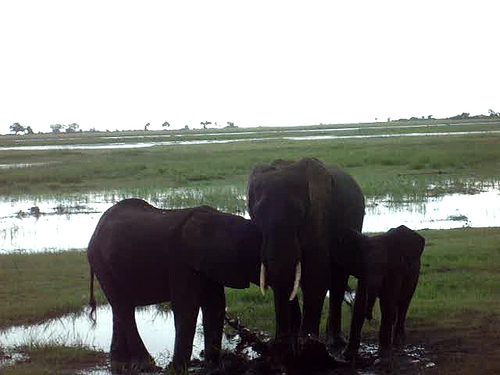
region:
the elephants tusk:
[290, 267, 308, 297]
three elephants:
[87, 153, 438, 366]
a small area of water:
[37, 309, 100, 346]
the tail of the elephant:
[82, 265, 96, 316]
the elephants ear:
[304, 152, 344, 219]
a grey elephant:
[94, 200, 241, 302]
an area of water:
[385, 180, 498, 229]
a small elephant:
[352, 225, 423, 344]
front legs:
[172, 305, 234, 363]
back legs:
[105, 311, 160, 368]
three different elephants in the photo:
[104, 148, 454, 331]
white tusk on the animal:
[283, 252, 313, 305]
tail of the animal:
[71, 264, 108, 323]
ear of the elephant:
[301, 158, 336, 210]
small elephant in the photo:
[346, 207, 416, 314]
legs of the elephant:
[75, 300, 235, 365]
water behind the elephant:
[440, 190, 480, 225]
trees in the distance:
[30, 110, 220, 145]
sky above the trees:
[265, 85, 310, 115]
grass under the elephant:
[435, 268, 477, 318]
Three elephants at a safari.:
[71, 141, 446, 371]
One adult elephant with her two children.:
[70, 128, 444, 368]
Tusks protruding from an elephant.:
[252, 239, 317, 306]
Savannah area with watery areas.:
[7, 114, 496, 328]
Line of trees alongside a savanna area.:
[3, 108, 498, 132]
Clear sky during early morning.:
[4, 40, 489, 118]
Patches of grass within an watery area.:
[370, 158, 482, 217]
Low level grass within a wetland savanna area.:
[405, 230, 492, 320]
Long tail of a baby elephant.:
[70, 246, 112, 338]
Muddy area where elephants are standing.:
[275, 320, 429, 373]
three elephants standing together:
[86, 148, 434, 368]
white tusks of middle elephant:
[247, 253, 319, 298]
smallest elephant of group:
[347, 218, 422, 355]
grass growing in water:
[43, 173, 471, 231]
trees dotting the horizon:
[8, 111, 494, 128]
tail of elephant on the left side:
[82, 255, 102, 314]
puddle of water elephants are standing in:
[7, 291, 398, 373]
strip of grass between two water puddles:
[12, 248, 489, 315]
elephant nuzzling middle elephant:
[87, 198, 269, 360]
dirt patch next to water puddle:
[355, 313, 495, 373]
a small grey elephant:
[86, 195, 258, 369]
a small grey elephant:
[346, 223, 426, 355]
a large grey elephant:
[246, 160, 366, 367]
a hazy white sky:
[0, 0, 497, 135]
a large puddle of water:
[0, 194, 190, 254]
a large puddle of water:
[2, 297, 268, 365]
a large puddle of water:
[354, 182, 499, 234]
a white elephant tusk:
[290, 255, 301, 299]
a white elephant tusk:
[259, 261, 266, 296]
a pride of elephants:
[83, 157, 422, 373]